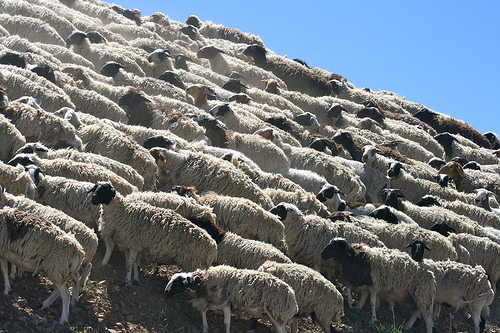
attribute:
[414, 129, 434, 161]
ground — white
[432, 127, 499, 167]
sheep — white, dirty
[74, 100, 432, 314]
sheep — gathered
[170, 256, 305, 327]
sheep — white, dirty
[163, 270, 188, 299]
head — black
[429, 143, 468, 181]
ground — dirty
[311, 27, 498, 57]
sky — blue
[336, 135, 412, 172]
animal — brown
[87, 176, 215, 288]
sheep — dirty, white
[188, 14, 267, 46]
sheep — distant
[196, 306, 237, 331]
leg — hind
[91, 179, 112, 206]
head — black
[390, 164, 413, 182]
head — black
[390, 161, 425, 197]
sheep — white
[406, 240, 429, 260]
head — black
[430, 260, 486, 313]
sheep — dirty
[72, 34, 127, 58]
sheep — white, dirty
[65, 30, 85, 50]
head — black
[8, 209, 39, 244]
spot — brown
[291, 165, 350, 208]
face — white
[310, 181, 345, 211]
spots — black